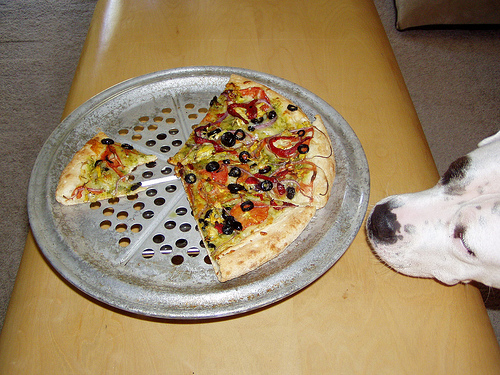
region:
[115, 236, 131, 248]
whole in pizza plan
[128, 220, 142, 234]
whole in pizza plan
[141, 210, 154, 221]
whole in pizza plan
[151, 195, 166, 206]
whole in pizza plan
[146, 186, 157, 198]
whole in pizza plan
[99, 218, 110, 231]
whole in pizza plan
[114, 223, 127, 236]
whole in pizza plan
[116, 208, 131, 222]
whole in pizza plan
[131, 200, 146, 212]
whole in pizza plan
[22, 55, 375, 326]
tray is color silver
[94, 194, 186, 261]
holes in a silver tray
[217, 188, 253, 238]
black olives on a pizza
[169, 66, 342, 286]
three slices of pizza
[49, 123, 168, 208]
half of a pizza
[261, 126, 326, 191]
slices of onions on pizza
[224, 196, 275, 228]
a slice of red tomato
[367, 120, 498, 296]
the head of dog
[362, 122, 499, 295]
the head of a dog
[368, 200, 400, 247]
nose of dog is black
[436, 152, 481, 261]
eyes of dog are closed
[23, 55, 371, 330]
a tray with pizza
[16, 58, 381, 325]
tray is color silver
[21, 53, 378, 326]
the tray has holes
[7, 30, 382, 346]
tray is on a table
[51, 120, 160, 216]
pizza is cut pizza is half eaten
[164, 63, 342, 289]
three slices of pizza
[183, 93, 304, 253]
olives on top a pizza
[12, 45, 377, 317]
the pizza is on the table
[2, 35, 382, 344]
the pizza is on a tray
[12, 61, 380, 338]
the tray is silver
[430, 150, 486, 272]
the eyes are closed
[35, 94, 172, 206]
a piece of pizza is eaten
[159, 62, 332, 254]
a pizza with everything on it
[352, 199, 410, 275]
the nose is black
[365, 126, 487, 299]
the dog is white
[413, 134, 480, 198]
the eye fur is black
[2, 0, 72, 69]
the carpet is beige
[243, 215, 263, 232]
topping on the pizza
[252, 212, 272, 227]
topping on the pizza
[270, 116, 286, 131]
topping on the pizza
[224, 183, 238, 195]
topping on the pizza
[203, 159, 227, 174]
topping on the pizza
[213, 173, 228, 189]
topping on the pizza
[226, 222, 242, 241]
topping on the pizza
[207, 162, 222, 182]
topping on the pizza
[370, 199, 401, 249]
Nose of a dog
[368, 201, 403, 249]
Black nose of a dog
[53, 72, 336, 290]
Pieces of pizza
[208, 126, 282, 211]
Toppings on a pizza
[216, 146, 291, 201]
Toppings on a pizza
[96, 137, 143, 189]
Toppings on a pizza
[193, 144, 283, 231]
Toppings on a pizza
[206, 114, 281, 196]
Toppings on a pizza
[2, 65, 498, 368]
Close-up, showing furniture, food and animal.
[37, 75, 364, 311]
Circular, metal pan with round holes.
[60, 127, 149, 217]
Single, half-eaten slice of pizza.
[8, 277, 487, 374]
Tan, bench-like surface, holding plate with pizza.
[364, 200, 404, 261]
Black nose of dog, near dish.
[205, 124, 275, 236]
Black olives, interspersed on red and green toppings of pizza.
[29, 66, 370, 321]
Pieces of pizza crust